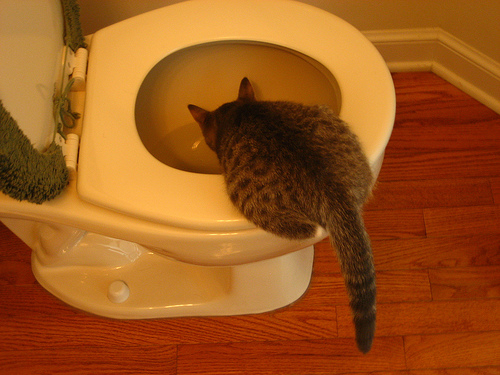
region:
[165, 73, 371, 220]
Cat in the toilet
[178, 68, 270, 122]
cat ears perked up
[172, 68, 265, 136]
cat head in the toilet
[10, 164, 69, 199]
green cover on a toilet seat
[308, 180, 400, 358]
cat with a long tail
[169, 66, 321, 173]
cat drinking from the water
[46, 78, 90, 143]
string tied on the toilet seat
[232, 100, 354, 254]
cat with gray and black fur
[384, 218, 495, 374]
wood floor in the bathroom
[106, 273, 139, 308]
knob on a table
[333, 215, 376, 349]
The tail of the cat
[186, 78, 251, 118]
The ears of the cat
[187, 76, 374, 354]
The cat is on the toilet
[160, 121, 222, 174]
Water in the toilet bowl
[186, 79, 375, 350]
The cat is black and brown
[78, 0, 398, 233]
The seat of the toilet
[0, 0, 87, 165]
The lid of the toilet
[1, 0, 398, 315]
A toilet beneath the cat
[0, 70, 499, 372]
The floor beneath the toilet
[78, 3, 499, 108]
The wall next to the toilet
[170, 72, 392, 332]
a cat drinking out of a toilet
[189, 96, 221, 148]
the ear of a cat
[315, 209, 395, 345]
the tail of a cat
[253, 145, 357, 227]
the hind end of a cat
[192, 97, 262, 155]
the head of a cat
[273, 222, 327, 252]
the back paw of a cat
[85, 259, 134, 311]
the white bolt of a toilet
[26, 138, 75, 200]
a green fuzzy toilet seat cover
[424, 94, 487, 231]
a brown hard wood floor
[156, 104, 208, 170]
the water in a toilet bowl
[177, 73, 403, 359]
cat sitting on the toilet bowl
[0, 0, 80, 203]
toilet lid is up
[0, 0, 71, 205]
green toilet seat cover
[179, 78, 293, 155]
cat's head in the toilet bowl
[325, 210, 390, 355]
tail is hanging down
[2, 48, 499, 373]
light brown wood on the floor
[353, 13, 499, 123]
white trim on the bottom of the wall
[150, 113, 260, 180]
water in the bowl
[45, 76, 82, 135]
ribbon tied in a bow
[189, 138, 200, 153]
light glare in the toilet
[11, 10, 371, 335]
the toilet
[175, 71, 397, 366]
cat peering into the toilet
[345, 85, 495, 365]
the floor is wooden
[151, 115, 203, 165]
water in the toilet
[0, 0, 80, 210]
the toilet lid is up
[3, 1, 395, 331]
the toilet is white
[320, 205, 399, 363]
the tail of the cat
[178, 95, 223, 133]
the ear of the cat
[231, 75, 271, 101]
the ear of the cat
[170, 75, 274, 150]
the head of the cat